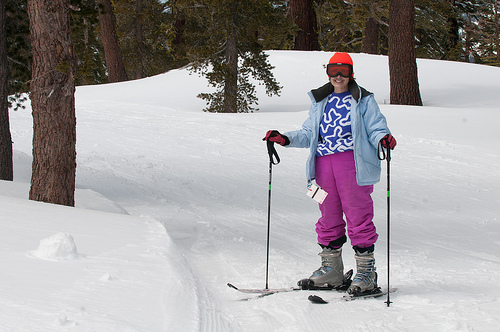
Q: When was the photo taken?
A: Daytime.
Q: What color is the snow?
A: White.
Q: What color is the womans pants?
A: Purple.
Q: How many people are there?
A: One.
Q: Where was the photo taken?
A: In the mountains.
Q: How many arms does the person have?
A: Two.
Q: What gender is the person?
A: Female.